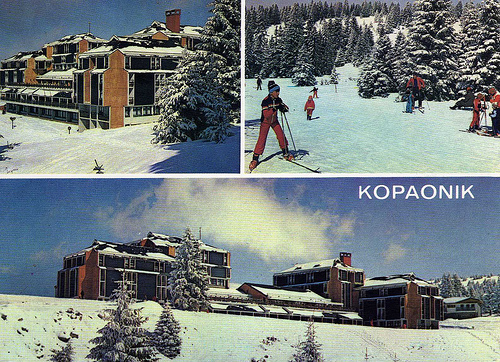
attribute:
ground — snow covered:
[245, 77, 484, 173]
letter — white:
[356, 180, 371, 200]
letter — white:
[372, 183, 392, 199]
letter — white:
[389, 181, 407, 200]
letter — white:
[403, 183, 422, 201]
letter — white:
[418, 182, 438, 201]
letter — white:
[438, 181, 453, 201]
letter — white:
[458, 182, 477, 199]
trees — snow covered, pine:
[84, 271, 183, 360]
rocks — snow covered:
[44, 302, 84, 342]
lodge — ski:
[51, 229, 444, 329]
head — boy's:
[266, 79, 282, 101]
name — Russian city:
[356, 180, 475, 203]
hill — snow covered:
[0, 291, 484, 360]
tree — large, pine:
[164, 225, 214, 315]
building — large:
[52, 230, 443, 330]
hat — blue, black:
[263, 74, 305, 97]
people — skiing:
[268, 77, 494, 147]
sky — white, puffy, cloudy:
[146, 196, 434, 295]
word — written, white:
[352, 174, 494, 221]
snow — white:
[246, 317, 433, 357]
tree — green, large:
[72, 283, 155, 353]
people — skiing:
[235, 39, 453, 169]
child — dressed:
[278, 73, 338, 120]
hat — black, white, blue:
[263, 77, 301, 108]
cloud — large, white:
[155, 183, 375, 272]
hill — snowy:
[256, 25, 452, 160]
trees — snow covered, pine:
[290, 16, 482, 106]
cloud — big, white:
[108, 194, 303, 259]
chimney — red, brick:
[144, 5, 188, 38]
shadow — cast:
[129, 130, 232, 181]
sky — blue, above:
[86, 185, 445, 275]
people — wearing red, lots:
[243, 56, 498, 176]